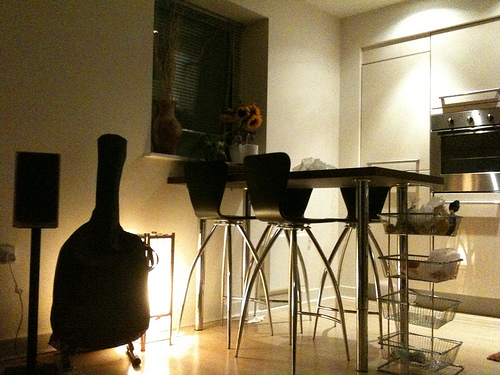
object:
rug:
[481, 346, 498, 360]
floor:
[4, 292, 497, 372]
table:
[191, 165, 447, 371]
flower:
[218, 104, 264, 135]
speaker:
[14, 151, 66, 360]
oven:
[429, 88, 499, 193]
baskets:
[378, 198, 464, 237]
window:
[156, 1, 243, 151]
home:
[0, 3, 494, 373]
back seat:
[242, 152, 289, 222]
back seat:
[183, 155, 229, 217]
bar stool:
[234, 151, 353, 372]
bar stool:
[313, 185, 404, 349]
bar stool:
[176, 160, 275, 337]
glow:
[121, 228, 197, 374]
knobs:
[447, 113, 493, 124]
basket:
[378, 247, 464, 282]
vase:
[154, 96, 184, 156]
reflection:
[153, 310, 204, 365]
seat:
[183, 156, 260, 222]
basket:
[378, 289, 463, 329]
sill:
[145, 153, 190, 160]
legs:
[179, 221, 415, 362]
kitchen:
[6, 4, 498, 369]